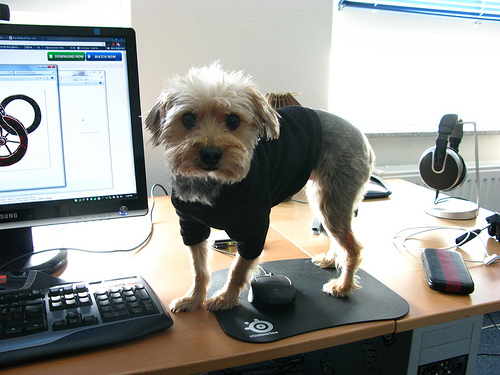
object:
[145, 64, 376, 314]
dog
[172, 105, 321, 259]
shirt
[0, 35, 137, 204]
computer screen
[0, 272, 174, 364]
keyboard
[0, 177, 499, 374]
desk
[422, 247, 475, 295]
phone case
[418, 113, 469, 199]
headphones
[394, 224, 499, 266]
cord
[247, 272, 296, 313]
computer mouse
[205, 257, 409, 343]
mouse pad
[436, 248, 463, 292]
stripe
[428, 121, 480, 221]
stand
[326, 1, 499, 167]
window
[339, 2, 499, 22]
blinds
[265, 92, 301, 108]
lampshade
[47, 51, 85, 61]
button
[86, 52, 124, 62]
button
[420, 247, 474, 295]
cellphone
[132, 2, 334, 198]
wall